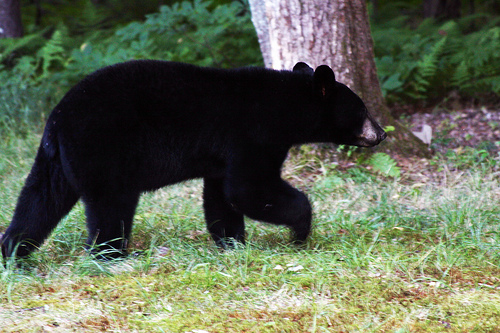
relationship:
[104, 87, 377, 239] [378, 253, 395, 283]
bear walking on grass